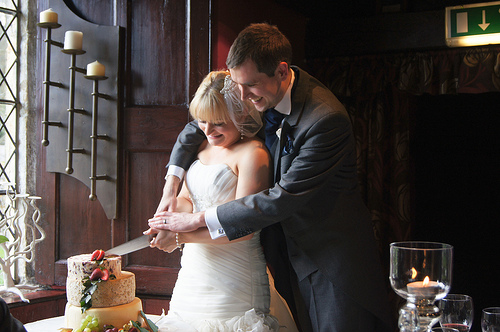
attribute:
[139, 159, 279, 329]
dress — wedding, bottom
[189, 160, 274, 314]
dress — white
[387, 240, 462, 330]
candle holder — large, glass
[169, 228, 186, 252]
bracelet — white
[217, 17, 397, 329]
man — nose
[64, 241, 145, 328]
cake — small, layered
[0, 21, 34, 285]
window — long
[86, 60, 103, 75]
candle — beige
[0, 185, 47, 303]
tree — white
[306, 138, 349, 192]
coat — black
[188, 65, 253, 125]
hair — blonde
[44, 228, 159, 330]
knife — cutting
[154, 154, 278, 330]
dress — a wedding dress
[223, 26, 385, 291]
man — eyes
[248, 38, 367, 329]
man — mouth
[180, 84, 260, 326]
woman — head